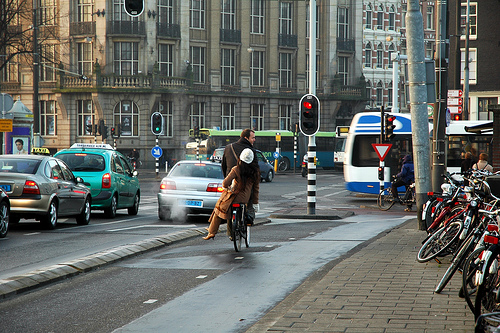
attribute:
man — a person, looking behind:
[220, 127, 258, 176]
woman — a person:
[202, 146, 262, 246]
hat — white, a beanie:
[238, 147, 256, 165]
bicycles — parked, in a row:
[414, 165, 500, 333]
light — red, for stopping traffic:
[301, 98, 313, 113]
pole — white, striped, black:
[306, 144, 318, 205]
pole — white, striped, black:
[293, 133, 298, 160]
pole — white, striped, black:
[154, 137, 163, 175]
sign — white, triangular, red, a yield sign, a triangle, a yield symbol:
[371, 140, 394, 163]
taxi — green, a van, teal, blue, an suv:
[50, 142, 142, 218]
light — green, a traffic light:
[155, 126, 161, 133]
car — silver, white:
[157, 158, 227, 226]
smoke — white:
[167, 197, 191, 223]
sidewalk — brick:
[254, 215, 494, 331]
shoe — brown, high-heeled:
[202, 232, 217, 245]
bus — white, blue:
[342, 110, 498, 201]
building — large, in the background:
[1, 1, 358, 173]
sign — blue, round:
[150, 145, 164, 160]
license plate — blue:
[181, 199, 204, 209]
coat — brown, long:
[220, 165, 261, 207]